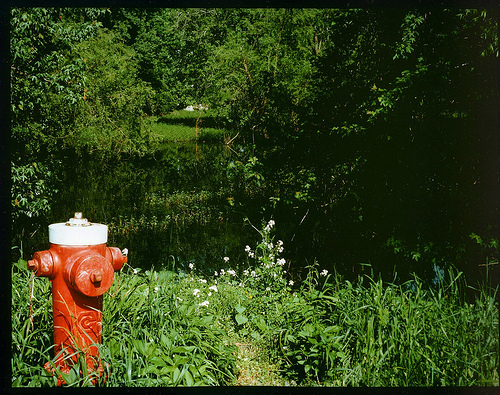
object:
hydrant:
[27, 205, 128, 386]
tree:
[9, 3, 76, 256]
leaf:
[24, 25, 30, 32]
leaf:
[25, 211, 32, 217]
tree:
[212, 35, 280, 243]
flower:
[432, 263, 445, 285]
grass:
[263, 282, 495, 350]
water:
[42, 153, 402, 277]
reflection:
[88, 163, 157, 187]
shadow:
[160, 118, 231, 130]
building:
[183, 103, 208, 111]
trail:
[226, 334, 282, 392]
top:
[46, 209, 110, 246]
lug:
[90, 270, 105, 285]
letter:
[79, 312, 97, 330]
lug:
[66, 212, 92, 227]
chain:
[28, 272, 34, 343]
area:
[11, 253, 497, 385]